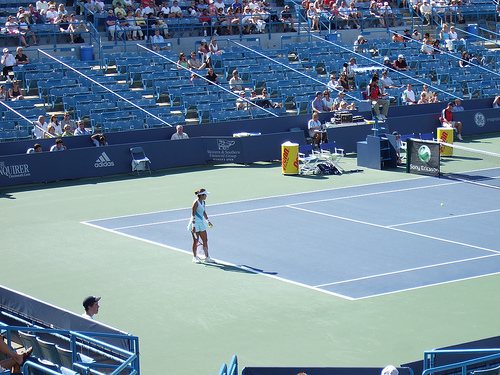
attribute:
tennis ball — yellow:
[207, 222, 213, 227]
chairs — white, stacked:
[294, 149, 351, 188]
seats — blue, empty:
[58, 55, 231, 117]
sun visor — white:
[198, 189, 210, 196]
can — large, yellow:
[280, 142, 300, 177]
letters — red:
[281, 145, 291, 172]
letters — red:
[292, 153, 299, 170]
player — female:
[184, 181, 219, 273]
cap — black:
[80, 290, 102, 305]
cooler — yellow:
[277, 138, 303, 178]